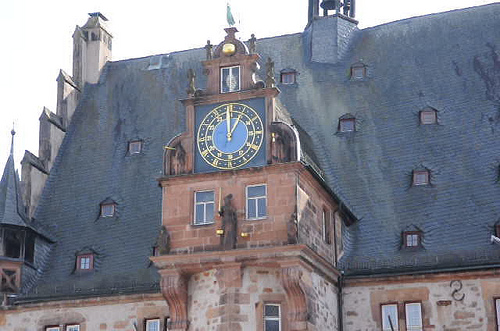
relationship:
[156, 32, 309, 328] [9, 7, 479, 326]
clock tower on building